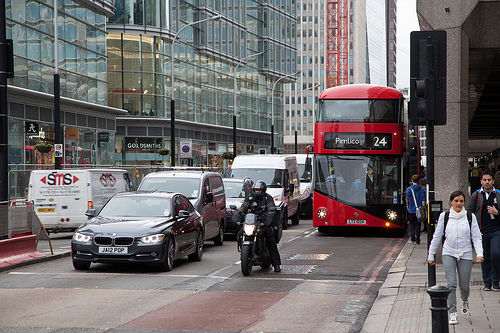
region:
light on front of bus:
[304, 188, 351, 231]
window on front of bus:
[301, 142, 406, 219]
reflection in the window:
[306, 144, 398, 222]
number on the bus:
[363, 124, 398, 159]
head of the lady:
[433, 180, 475, 217]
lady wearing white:
[421, 188, 491, 280]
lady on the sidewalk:
[418, 175, 481, 264]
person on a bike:
[222, 174, 311, 261]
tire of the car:
[152, 233, 186, 278]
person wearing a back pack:
[415, 183, 485, 328]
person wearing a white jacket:
[408, 178, 490, 331]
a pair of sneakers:
[438, 282, 482, 325]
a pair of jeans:
[432, 247, 479, 327]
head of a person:
[442, 180, 470, 218]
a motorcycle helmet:
[243, 169, 277, 199]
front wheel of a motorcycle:
[228, 234, 262, 280]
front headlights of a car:
[70, 223, 171, 263]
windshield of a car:
[92, 187, 189, 224]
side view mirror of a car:
[180, 204, 190, 221]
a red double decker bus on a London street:
[310, 80, 410, 235]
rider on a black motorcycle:
[236, 178, 284, 277]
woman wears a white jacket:
[428, 187, 485, 325]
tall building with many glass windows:
[0, 1, 298, 242]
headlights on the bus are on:
[313, 205, 400, 221]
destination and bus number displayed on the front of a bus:
[332, 135, 389, 148]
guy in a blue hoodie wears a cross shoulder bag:
[403, 173, 428, 247]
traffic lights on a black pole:
[408, 87, 450, 289]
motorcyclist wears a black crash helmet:
[233, 180, 286, 276]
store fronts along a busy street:
[1, 114, 276, 219]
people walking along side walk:
[405, 158, 492, 323]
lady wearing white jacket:
[418, 183, 498, 268]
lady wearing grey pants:
[429, 239, 488, 331]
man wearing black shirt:
[451, 168, 498, 233]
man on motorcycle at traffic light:
[222, 174, 289, 295]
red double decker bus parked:
[288, 40, 420, 249]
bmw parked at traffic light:
[72, 177, 214, 288]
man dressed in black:
[234, 166, 296, 273]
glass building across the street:
[9, 8, 331, 181]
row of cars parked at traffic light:
[141, 148, 331, 254]